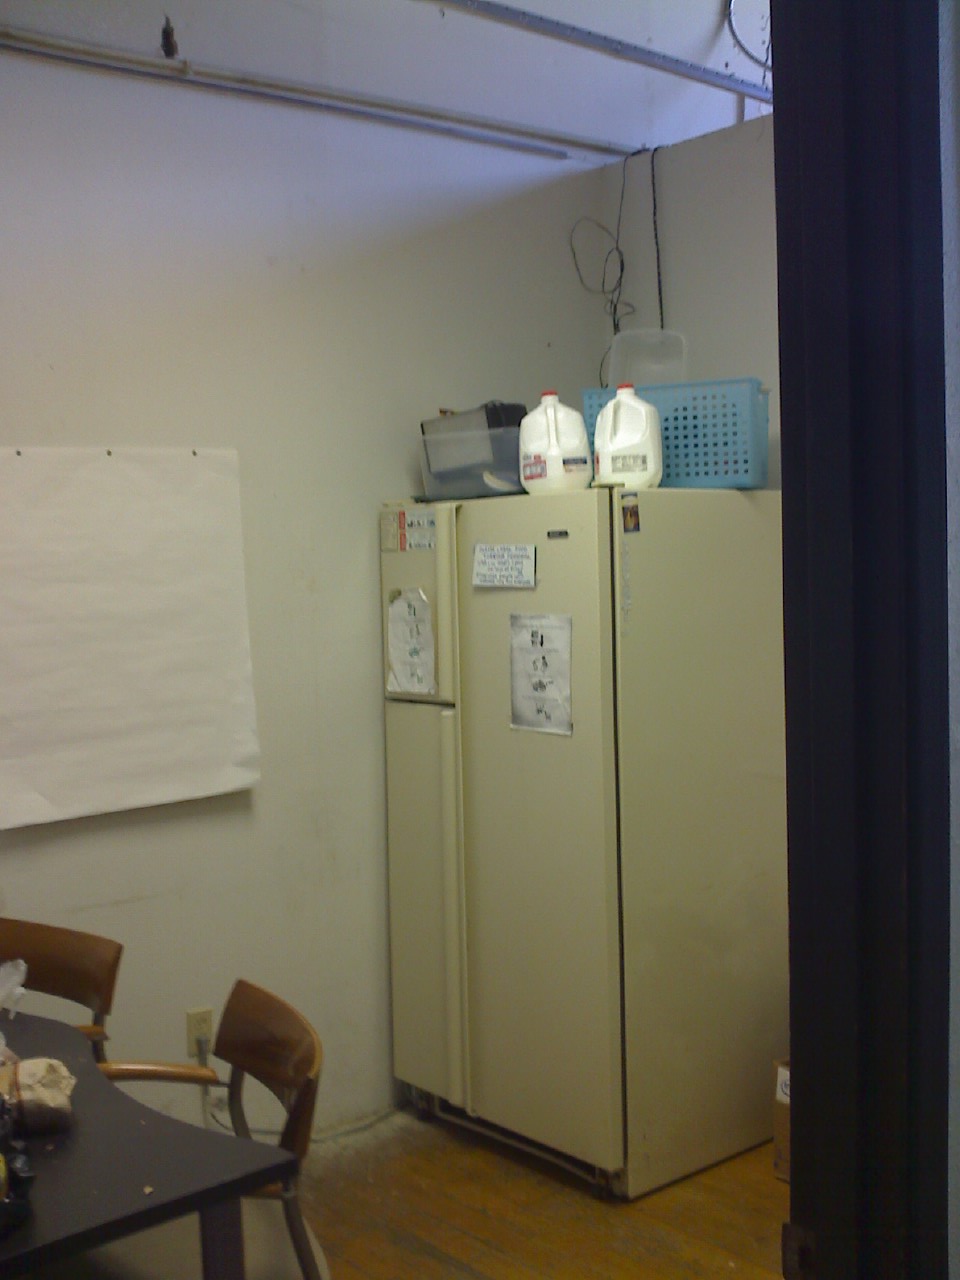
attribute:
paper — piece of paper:
[499, 603, 568, 729]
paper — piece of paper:
[615, 485, 628, 524]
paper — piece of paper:
[385, 509, 441, 547]